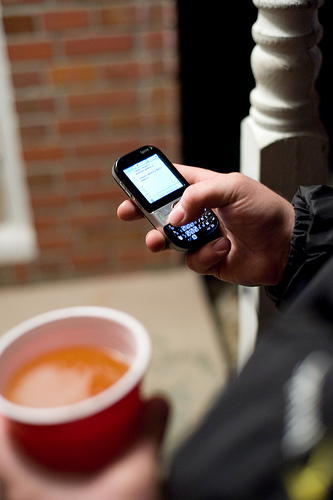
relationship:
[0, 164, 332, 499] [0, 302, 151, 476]
man holds red cup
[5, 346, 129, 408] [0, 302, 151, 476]
orange liquid in cup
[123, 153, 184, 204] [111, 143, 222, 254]
lcd screen on phone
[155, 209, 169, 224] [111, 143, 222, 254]
grey buttons on phone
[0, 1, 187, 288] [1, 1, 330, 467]
brick wall in background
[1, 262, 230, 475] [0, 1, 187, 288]
grey floor under brick wall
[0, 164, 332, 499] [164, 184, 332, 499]
person has black coat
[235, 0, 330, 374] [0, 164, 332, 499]
white rail behind person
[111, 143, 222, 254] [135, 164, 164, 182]
cell phone with text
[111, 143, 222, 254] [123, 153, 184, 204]
cell phone with lcd screen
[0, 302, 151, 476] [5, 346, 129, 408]
cup with orange liquid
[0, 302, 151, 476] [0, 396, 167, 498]
red cup with hand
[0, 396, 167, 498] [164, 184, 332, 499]
hand with jacket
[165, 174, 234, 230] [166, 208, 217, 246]
thumb texting buttons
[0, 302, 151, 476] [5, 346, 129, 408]
cup with beverage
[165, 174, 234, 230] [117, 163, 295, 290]
thumb on right hand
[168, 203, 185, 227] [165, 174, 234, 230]
thumbnail on thumb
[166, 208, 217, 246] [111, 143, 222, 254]
keyboard on cell phone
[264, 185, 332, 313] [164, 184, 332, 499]
sleeve of black jacket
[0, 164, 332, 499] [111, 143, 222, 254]
person holding cell phone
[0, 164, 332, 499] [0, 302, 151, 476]
person holding cup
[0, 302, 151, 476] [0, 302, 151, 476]
white rim on cup